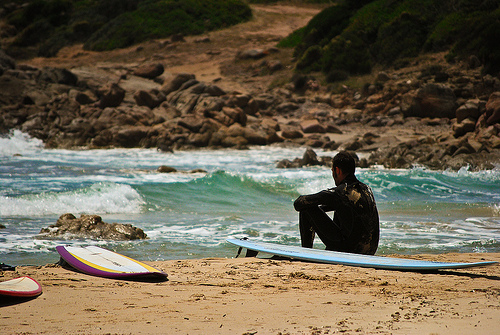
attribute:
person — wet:
[292, 147, 379, 254]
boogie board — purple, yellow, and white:
[55, 243, 170, 283]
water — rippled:
[0, 123, 500, 269]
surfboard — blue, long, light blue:
[223, 232, 498, 270]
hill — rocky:
[0, 2, 500, 162]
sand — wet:
[124, 284, 468, 322]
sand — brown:
[56, 286, 491, 329]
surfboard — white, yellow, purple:
[56, 246, 165, 278]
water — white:
[2, 188, 137, 215]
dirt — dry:
[137, 32, 213, 57]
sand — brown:
[4, 268, 465, 330]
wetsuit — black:
[295, 180, 378, 251]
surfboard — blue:
[227, 238, 497, 268]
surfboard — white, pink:
[2, 276, 40, 300]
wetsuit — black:
[295, 176, 380, 256]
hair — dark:
[330, 150, 355, 177]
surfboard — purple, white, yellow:
[58, 244, 167, 283]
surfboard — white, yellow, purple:
[56, 241, 167, 281]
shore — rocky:
[1, 1, 499, 171]